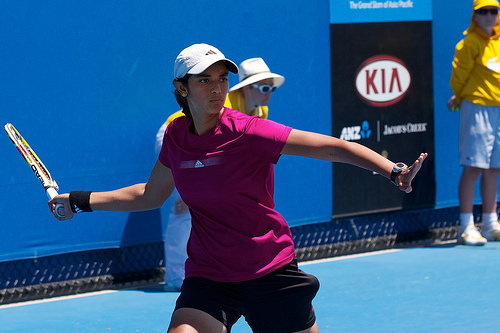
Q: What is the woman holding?
A: Tennis racket.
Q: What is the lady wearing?
A: Pink shirt and black shorts.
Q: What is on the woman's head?
A: Hat.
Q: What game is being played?
A: Tennis.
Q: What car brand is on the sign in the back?
A: Kia.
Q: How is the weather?
A: Sunny.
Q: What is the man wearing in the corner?
A: Yellow sweatshirt.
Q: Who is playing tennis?
A: A woman.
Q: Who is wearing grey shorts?
A: Person on far right.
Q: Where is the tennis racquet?
A: Woman's right hand.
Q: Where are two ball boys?
A: Standing at back wall.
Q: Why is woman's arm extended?
A: For balance.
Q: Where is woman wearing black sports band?
A: On right wrist.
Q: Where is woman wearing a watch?
A: On left wrist.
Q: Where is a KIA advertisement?
A: On back wall.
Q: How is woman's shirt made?
A: Short sleeved.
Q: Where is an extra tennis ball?
A: Woman's left pocket.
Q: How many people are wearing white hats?
A: Two.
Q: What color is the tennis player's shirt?
A: Pink.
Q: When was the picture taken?
A: Daytime.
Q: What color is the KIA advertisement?
A: White and red.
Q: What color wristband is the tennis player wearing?
A: Black.